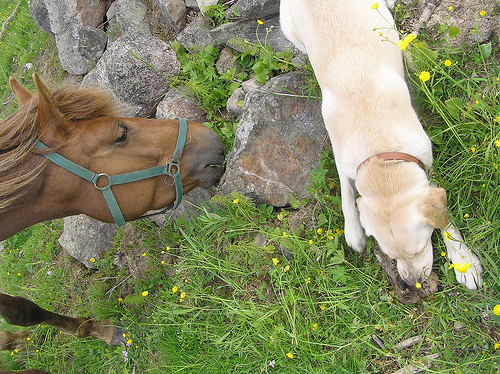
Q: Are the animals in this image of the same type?
A: No, they are horses and dogs.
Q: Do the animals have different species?
A: Yes, they are horses and dogs.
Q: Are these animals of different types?
A: Yes, they are horses and dogs.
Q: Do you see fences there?
A: No, there are no fences.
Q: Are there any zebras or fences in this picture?
A: No, there are no fences or zebras.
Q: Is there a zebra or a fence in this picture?
A: No, there are no fences or zebras.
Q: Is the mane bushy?
A: Yes, the mane is bushy.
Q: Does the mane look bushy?
A: Yes, the mane is bushy.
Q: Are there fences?
A: No, there are no fences.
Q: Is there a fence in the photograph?
A: No, there are no fences.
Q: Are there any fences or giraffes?
A: No, there are no fences or giraffes.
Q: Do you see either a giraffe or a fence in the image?
A: No, there are no fences or giraffes.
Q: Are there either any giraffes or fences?
A: No, there are no fences or giraffes.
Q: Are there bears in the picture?
A: No, there are no bears.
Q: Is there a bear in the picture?
A: No, there are no bears.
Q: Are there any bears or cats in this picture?
A: No, there are no bears or cats.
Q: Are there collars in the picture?
A: Yes, there is a collar.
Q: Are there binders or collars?
A: Yes, there is a collar.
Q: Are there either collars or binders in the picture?
A: Yes, there is a collar.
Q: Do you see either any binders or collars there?
A: Yes, there is a collar.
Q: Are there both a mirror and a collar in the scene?
A: No, there is a collar but no mirrors.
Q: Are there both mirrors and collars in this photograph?
A: No, there is a collar but no mirrors.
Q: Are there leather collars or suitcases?
A: Yes, there is a leather collar.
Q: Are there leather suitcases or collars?
A: Yes, there is a leather collar.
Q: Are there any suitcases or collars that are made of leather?
A: Yes, the collar is made of leather.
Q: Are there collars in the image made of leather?
A: Yes, there is a collar that is made of leather.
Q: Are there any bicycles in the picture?
A: No, there are no bicycles.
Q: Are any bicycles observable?
A: No, there are no bicycles.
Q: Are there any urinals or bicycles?
A: No, there are no bicycles or urinals.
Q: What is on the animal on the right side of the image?
A: The collar is on the dog.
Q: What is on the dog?
A: The collar is on the dog.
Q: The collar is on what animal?
A: The collar is on the dog.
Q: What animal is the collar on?
A: The collar is on the dog.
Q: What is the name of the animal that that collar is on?
A: The animal is a dog.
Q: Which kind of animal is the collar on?
A: The collar is on the dog.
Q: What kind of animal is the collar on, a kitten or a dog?
A: The collar is on a dog.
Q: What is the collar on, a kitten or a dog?
A: The collar is on a dog.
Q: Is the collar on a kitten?
A: No, the collar is on the dog.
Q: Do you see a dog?
A: Yes, there is a dog.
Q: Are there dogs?
A: Yes, there is a dog.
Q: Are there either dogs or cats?
A: Yes, there is a dog.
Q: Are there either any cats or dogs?
A: Yes, there is a dog.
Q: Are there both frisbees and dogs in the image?
A: No, there is a dog but no frisbees.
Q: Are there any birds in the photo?
A: No, there are no birds.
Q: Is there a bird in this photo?
A: No, there are no birds.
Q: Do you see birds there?
A: No, there are no birds.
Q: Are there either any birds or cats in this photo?
A: No, there are no birds or cats.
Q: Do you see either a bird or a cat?
A: No, there are no birds or cats.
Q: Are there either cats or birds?
A: No, there are no birds or cats.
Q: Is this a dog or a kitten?
A: This is a dog.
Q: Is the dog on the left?
A: No, the dog is on the right of the image.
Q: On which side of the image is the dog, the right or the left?
A: The dog is on the right of the image.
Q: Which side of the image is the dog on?
A: The dog is on the right of the image.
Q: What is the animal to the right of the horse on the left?
A: The animal is a dog.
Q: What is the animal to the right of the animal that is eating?
A: The animal is a dog.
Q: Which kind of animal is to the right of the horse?
A: The animal is a dog.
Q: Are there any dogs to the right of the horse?
A: Yes, there is a dog to the right of the horse.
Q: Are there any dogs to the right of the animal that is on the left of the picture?
A: Yes, there is a dog to the right of the horse.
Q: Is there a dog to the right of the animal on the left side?
A: Yes, there is a dog to the right of the horse.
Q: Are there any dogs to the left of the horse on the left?
A: No, the dog is to the right of the horse.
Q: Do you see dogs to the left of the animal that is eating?
A: No, the dog is to the right of the horse.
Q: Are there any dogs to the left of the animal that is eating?
A: No, the dog is to the right of the horse.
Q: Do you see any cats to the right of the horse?
A: No, there is a dog to the right of the horse.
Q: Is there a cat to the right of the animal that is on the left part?
A: No, there is a dog to the right of the horse.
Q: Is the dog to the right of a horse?
A: Yes, the dog is to the right of a horse.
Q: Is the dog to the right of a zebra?
A: No, the dog is to the right of a horse.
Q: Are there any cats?
A: No, there are no cats.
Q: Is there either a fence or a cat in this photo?
A: No, there are no cats or fences.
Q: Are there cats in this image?
A: No, there are no cats.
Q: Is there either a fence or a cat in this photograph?
A: No, there are no cats or fences.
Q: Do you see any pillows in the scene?
A: No, there are no pillows.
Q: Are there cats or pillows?
A: No, there are no pillows or cats.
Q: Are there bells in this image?
A: No, there are no bells.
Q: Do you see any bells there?
A: No, there are no bells.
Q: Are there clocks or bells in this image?
A: No, there are no bells or clocks.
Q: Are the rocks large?
A: Yes, the rocks are large.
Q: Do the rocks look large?
A: Yes, the rocks are large.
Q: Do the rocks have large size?
A: Yes, the rocks are large.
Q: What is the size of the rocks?
A: The rocks are large.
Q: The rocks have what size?
A: The rocks are large.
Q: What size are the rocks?
A: The rocks are large.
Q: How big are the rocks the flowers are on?
A: The rocks are large.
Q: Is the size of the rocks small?
A: No, the rocks are large.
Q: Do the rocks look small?
A: No, the rocks are large.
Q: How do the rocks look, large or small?
A: The rocks are large.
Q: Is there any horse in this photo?
A: Yes, there is a horse.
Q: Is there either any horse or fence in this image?
A: Yes, there is a horse.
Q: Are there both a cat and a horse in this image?
A: No, there is a horse but no cats.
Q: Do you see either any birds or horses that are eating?
A: Yes, the horse is eating.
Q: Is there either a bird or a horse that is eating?
A: Yes, the horse is eating.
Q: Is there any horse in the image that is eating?
A: Yes, there is a horse that is eating.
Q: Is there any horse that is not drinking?
A: Yes, there is a horse that is eating.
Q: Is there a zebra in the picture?
A: No, there are no zebras.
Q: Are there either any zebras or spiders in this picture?
A: No, there are no zebras or spiders.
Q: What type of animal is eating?
A: The animal is a horse.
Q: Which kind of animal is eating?
A: The animal is a horse.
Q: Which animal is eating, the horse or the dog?
A: The horse is eating.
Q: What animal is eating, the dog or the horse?
A: The horse is eating.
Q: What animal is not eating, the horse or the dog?
A: The dog is not eating.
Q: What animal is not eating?
A: The animal is a dog.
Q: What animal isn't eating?
A: The animal is a dog.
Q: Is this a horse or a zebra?
A: This is a horse.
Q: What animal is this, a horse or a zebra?
A: This is a horse.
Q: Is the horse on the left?
A: Yes, the horse is on the left of the image.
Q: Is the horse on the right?
A: No, the horse is on the left of the image.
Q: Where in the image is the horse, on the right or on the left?
A: The horse is on the left of the image.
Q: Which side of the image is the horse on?
A: The horse is on the left of the image.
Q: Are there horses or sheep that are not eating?
A: No, there is a horse but it is eating.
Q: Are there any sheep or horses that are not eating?
A: No, there is a horse but it is eating.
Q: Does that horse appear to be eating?
A: Yes, the horse is eating.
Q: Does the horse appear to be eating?
A: Yes, the horse is eating.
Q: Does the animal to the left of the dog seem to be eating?
A: Yes, the horse is eating.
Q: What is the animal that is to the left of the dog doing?
A: The horse is eating.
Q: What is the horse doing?
A: The horse is eating.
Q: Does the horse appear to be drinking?
A: No, the horse is eating.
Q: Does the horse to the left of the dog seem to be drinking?
A: No, the horse is eating.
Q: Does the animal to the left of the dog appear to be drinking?
A: No, the horse is eating.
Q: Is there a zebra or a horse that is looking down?
A: No, there is a horse but it is eating.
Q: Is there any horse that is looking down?
A: No, there is a horse but it is eating.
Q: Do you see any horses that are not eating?
A: No, there is a horse but it is eating.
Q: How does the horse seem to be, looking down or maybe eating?
A: The horse is eating.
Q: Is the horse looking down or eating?
A: The horse is eating.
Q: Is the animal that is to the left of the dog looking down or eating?
A: The horse is eating.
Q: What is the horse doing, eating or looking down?
A: The horse is eating.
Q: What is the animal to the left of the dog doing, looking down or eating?
A: The horse is eating.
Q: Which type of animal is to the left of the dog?
A: The animal is a horse.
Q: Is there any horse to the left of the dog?
A: Yes, there is a horse to the left of the dog.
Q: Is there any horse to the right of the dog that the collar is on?
A: No, the horse is to the left of the dog.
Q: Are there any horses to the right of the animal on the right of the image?
A: No, the horse is to the left of the dog.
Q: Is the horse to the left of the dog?
A: Yes, the horse is to the left of the dog.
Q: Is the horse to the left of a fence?
A: No, the horse is to the left of the dog.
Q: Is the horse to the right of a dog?
A: No, the horse is to the left of a dog.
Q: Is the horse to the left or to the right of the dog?
A: The horse is to the left of the dog.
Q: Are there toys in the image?
A: No, there are no toys.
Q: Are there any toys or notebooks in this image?
A: No, there are no toys or notebooks.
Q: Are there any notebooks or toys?
A: No, there are no toys or notebooks.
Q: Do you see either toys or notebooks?
A: No, there are no toys or notebooks.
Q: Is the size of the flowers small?
A: Yes, the flowers are small.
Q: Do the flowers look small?
A: Yes, the flowers are small.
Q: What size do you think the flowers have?
A: The flowers have small size.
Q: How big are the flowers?
A: The flowers are small.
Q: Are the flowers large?
A: No, the flowers are small.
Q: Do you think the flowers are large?
A: No, the flowers are small.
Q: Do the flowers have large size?
A: No, the flowers are small.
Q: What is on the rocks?
A: The flowers are on the rocks.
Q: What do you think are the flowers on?
A: The flowers are on the rocks.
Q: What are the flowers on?
A: The flowers are on the rocks.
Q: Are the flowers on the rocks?
A: Yes, the flowers are on the rocks.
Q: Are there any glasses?
A: No, there are no glasses.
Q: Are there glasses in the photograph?
A: No, there are no glasses.